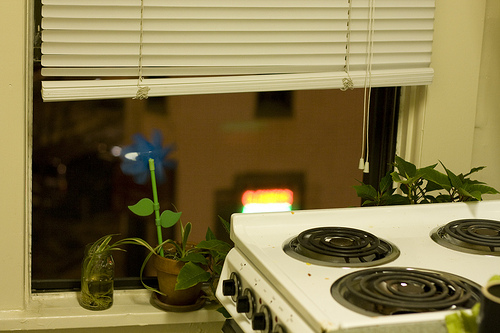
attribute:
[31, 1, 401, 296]
window — closed, glass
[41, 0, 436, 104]
mini blinds — off white, white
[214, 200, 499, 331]
stove — electric powered, white, electrical, old, electric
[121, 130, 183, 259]
flower — green, plastic, blue, blue plastic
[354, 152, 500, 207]
plant — green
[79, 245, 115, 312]
jar — glass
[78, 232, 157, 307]
plant — dying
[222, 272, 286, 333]
knobs — black, silver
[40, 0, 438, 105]
blinds — white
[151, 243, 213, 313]
pot — clay, small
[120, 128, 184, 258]
plant — blue, plastic, fake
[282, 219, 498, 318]
burners — black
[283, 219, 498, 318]
stove burners — electric, black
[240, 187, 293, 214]
sign — brightly lit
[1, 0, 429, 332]
window frame — white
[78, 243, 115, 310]
glass bottle — small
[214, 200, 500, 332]
range — white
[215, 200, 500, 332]
electric range — white